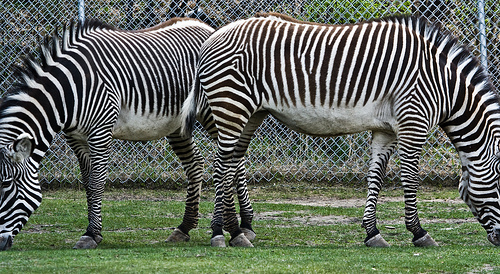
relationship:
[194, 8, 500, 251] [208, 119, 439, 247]
zebra has legs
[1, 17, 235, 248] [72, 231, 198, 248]
zebra has hooves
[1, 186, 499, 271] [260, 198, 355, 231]
grass has dirt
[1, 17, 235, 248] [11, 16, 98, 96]
zebra has mane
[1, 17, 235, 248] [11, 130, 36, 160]
zebra has ear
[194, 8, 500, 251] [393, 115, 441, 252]
zebra has leg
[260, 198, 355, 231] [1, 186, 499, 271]
dirt on grass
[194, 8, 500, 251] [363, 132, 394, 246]
zebra has leg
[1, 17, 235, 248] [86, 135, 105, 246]
zebra has leg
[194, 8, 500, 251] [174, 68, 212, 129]
zebra has tail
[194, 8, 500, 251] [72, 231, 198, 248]
zebra has hooves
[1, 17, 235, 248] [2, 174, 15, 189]
zebra has eye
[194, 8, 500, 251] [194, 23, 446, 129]
zebra has stripes